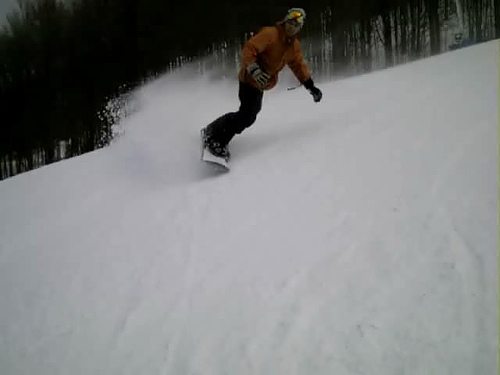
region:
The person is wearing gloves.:
[243, 60, 270, 87]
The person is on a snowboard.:
[201, 125, 230, 170]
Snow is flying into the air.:
[108, 58, 238, 178]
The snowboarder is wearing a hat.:
[285, 5, 305, 25]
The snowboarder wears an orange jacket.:
[237, 24, 312, 91]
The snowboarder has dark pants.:
[203, 78, 264, 146]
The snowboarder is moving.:
[198, 6, 323, 171]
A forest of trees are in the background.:
[0, 0, 499, 177]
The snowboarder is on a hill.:
[1, 38, 498, 374]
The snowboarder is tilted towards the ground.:
[201, 6, 321, 172]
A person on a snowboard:
[198, 8, 323, 154]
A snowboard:
[198, 127, 226, 167]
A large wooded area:
[0, 1, 497, 181]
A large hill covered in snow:
[1, 39, 496, 374]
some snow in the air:
[100, 55, 236, 183]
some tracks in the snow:
[247, 188, 481, 374]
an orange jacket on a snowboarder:
[228, 27, 308, 89]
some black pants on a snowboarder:
[203, 83, 265, 143]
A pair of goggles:
[288, 9, 305, 22]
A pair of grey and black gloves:
[246, 65, 323, 103]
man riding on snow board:
[198, 8, 318, 179]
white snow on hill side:
[11, 181, 123, 248]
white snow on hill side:
[32, 241, 109, 286]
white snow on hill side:
[56, 271, 151, 351]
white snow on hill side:
[168, 279, 275, 343]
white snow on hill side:
[265, 289, 340, 354]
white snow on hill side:
[339, 271, 409, 338]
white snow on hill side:
[409, 231, 474, 319]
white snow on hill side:
[228, 195, 316, 282]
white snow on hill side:
[349, 136, 434, 227]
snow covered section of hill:
[4, 39, 498, 373]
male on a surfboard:
[195, 6, 320, 171]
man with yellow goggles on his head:
[198, 6, 326, 168]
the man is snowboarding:
[197, 8, 322, 165]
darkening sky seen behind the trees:
[0, 0, 73, 45]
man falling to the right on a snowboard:
[200, 6, 323, 169]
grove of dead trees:
[235, 0, 495, 81]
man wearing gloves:
[200, 6, 325, 167]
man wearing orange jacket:
[200, 7, 326, 169]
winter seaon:
[1, 4, 496, 369]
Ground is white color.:
[106, 192, 266, 326]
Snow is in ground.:
[111, 213, 358, 332]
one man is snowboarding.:
[181, 10, 329, 200]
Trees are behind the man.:
[6, 25, 437, 102]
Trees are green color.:
[13, 32, 90, 103]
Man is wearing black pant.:
[197, 74, 264, 185]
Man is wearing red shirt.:
[240, 23, 320, 115]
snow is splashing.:
[120, 63, 215, 140]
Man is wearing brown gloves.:
[233, 56, 324, 112]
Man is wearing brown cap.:
[274, 8, 306, 38]